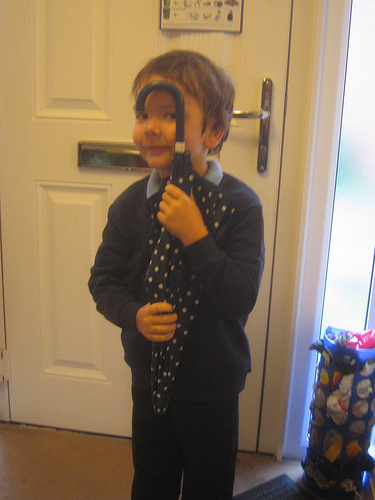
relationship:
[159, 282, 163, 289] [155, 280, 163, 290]
dot next to polkadot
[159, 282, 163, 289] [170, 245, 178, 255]
dot next to polkadot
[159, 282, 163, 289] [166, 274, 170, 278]
dot next to polkadot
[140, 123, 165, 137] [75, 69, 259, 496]
nose of boy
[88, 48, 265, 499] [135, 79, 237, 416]
boy holding an umbrella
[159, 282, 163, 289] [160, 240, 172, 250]
dot next polkadot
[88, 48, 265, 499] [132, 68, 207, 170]
boy has face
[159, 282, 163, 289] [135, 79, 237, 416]
dot on umbrella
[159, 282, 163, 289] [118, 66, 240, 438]
dot on umbrealla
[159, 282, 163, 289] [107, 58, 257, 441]
dot on umbrealla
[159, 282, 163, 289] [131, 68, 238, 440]
dot on umbrella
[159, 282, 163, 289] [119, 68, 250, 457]
dot on umbrella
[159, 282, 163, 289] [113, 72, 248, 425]
dot on umbrella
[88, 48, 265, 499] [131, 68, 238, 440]
boy holding umbrella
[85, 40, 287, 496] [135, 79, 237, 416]
boy holding umbrella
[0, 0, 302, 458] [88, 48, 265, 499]
door behind boy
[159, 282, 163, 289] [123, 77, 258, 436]
dot on umbrella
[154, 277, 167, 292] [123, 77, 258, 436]
dot on umbrella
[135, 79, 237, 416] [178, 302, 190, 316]
umbrella has dot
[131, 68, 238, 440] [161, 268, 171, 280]
umbrella has dot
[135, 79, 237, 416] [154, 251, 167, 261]
umbrella has dot